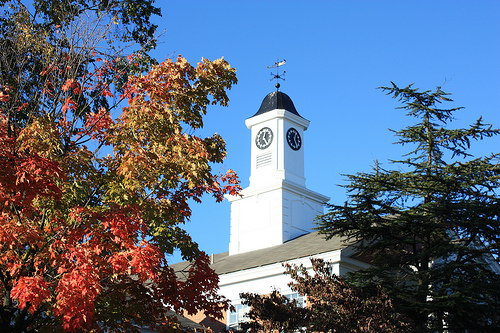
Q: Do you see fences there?
A: No, there are no fences.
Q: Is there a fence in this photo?
A: No, there are no fences.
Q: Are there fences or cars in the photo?
A: No, there are no fences or cars.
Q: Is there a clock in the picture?
A: Yes, there is a clock.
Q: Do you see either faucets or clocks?
A: Yes, there is a clock.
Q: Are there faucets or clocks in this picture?
A: Yes, there is a clock.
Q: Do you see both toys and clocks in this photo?
A: No, there is a clock but no toys.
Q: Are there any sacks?
A: No, there are no sacks.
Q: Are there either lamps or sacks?
A: No, there are no sacks or lamps.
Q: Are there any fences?
A: No, there are no fences.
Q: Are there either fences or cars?
A: No, there are no fences or cars.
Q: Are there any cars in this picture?
A: No, there are no cars.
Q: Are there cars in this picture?
A: No, there are no cars.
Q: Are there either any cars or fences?
A: No, there are no cars or fences.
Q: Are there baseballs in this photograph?
A: No, there are no baseballs.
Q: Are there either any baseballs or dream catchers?
A: No, there are no baseballs or dream catchers.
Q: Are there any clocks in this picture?
A: Yes, there is a clock.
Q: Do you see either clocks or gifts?
A: Yes, there is a clock.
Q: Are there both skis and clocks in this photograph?
A: No, there is a clock but no skis.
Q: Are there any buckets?
A: No, there are no buckets.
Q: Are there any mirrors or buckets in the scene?
A: No, there are no buckets or mirrors.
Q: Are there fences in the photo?
A: No, there are no fences.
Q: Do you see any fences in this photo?
A: No, there are no fences.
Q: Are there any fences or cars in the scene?
A: No, there are no fences or cars.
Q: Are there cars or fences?
A: No, there are no fences or cars.